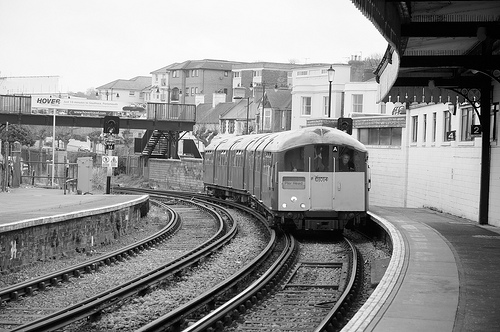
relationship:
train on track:
[200, 125, 373, 236] [2, 185, 361, 330]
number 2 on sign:
[470, 123, 480, 135] [231, 97, 399, 129]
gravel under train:
[218, 193, 360, 312] [200, 125, 373, 236]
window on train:
[312, 144, 331, 172] [200, 125, 373, 236]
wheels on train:
[267, 216, 278, 228] [196, 127, 382, 249]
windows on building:
[186, 70, 200, 100] [185, 59, 231, 104]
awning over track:
[369, 19, 490, 105] [2, 185, 361, 330]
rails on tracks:
[214, 282, 227, 290] [193, 237, 359, 330]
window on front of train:
[284, 143, 306, 174] [200, 125, 373, 236]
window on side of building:
[412, 112, 420, 142] [400, 99, 499, 226]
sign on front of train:
[272, 160, 336, 190] [96, 110, 407, 224]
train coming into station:
[196, 125, 381, 236] [328, 0, 498, 330]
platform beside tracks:
[369, 203, 498, 330] [139, 192, 266, 314]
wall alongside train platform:
[370, 136, 495, 227] [410, 213, 480, 305]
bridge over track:
[0, 94, 195, 157] [2, 185, 361, 330]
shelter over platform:
[347, 0, 498, 103] [335, 206, 498, 328]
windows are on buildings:
[163, 67, 197, 97] [148, 57, 233, 132]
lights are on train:
[277, 190, 314, 211] [196, 125, 381, 236]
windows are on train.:
[223, 150, 283, 188] [121, 89, 400, 264]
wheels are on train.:
[273, 209, 366, 235] [169, 95, 413, 265]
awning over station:
[373, 39, 490, 110] [0, 2, 497, 329]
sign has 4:
[423, 107, 473, 154] [446, 121, 456, 147]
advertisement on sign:
[30, 94, 124, 112] [18, 96, 124, 110]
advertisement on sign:
[30, 97, 124, 112] [14, 94, 128, 123]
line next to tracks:
[338, 210, 405, 330] [325, 207, 412, 330]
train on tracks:
[200, 125, 373, 236] [178, 230, 355, 330]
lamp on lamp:
[326, 64, 336, 82] [326, 66, 336, 83]